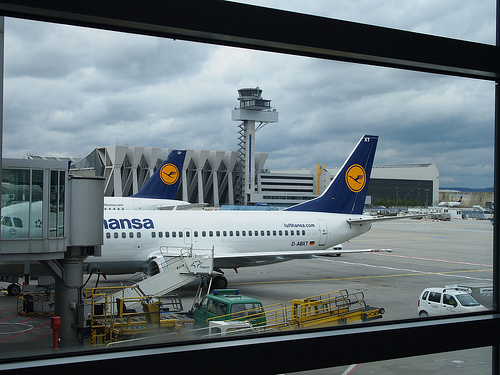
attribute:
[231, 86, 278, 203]
tower — air traffic control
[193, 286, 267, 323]
luggage truck — green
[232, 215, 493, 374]
tarmac — gray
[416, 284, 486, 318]
vehicle — airport security, white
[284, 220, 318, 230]
website address — for the airline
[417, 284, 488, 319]
van — white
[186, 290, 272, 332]
van — green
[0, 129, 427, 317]
plane — white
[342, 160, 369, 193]
logo — yellow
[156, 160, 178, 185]
logo — yellow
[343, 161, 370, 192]
logo — round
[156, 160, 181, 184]
logo — round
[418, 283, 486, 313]
vehicle — white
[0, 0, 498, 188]
clouds — stormy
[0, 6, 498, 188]
sky — stormy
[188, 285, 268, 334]
van — green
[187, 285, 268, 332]
vehicle — emergency, close by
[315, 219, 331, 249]
door — closed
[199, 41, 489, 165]
day — cloudy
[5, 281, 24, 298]
wheels — down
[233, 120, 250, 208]
stairwell — tall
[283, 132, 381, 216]
tail — blue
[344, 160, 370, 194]
circle — yellow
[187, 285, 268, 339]
van — green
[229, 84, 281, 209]
tower — tall, controller, overlooking, control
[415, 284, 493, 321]
car — white, compact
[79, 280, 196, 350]
loader — yellow, luggage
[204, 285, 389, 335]
loader — yellow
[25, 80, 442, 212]
airport terminal — grey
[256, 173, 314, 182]
windows — many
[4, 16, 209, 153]
sky — dark, cloudy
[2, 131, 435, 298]
airliner — white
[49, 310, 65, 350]
meter — red